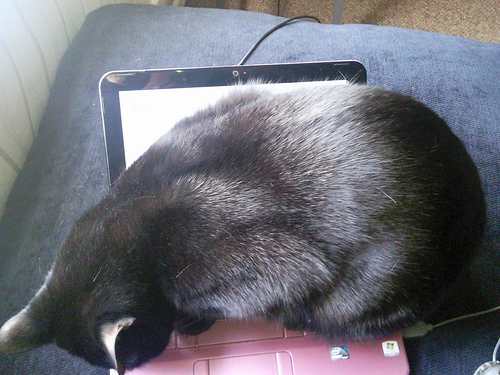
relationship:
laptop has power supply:
[96, 59, 409, 375] [206, 6, 332, 85]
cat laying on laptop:
[17, 78, 478, 361] [96, 43, 409, 369]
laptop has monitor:
[96, 59, 409, 375] [109, 68, 378, 188]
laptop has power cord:
[96, 43, 409, 369] [238, 3, 337, 82]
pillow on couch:
[3, 14, 497, 373] [2, 5, 493, 373]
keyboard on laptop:
[148, 276, 341, 332] [96, 43, 409, 369]